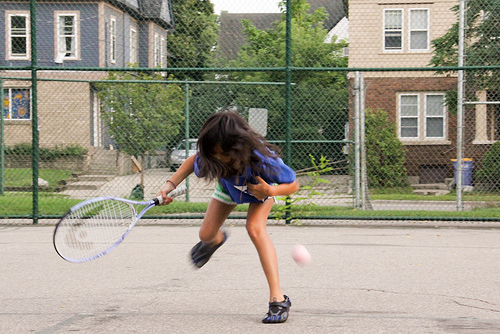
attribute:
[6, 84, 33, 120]
fabric — blue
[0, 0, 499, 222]
fence — green, chain link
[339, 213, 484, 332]
street — gray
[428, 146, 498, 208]
can — blue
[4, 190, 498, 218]
grass — green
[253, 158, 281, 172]
shirt — blue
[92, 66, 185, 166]
tree — green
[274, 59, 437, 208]
fence — green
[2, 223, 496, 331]
floor — concrete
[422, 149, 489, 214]
garbage — blue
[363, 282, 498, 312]
crack — large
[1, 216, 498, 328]
pavement — asphalt, cracked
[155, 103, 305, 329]
girl — little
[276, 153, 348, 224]
weed — growing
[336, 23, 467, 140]
building — brown, tan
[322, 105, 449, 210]
fence — green